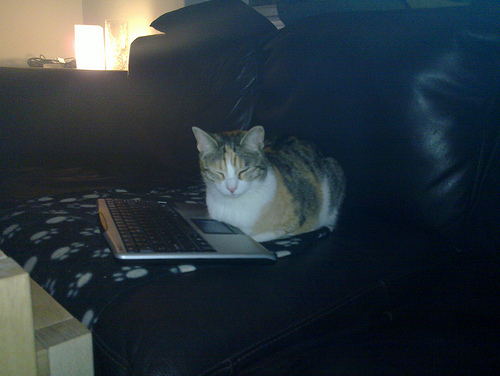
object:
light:
[73, 19, 150, 70]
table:
[1, 53, 97, 81]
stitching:
[201, 342, 256, 376]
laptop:
[94, 197, 278, 268]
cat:
[191, 125, 347, 248]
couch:
[1, 0, 499, 375]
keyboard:
[104, 197, 217, 254]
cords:
[24, 53, 75, 68]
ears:
[190, 123, 224, 153]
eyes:
[238, 167, 250, 179]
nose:
[225, 183, 239, 193]